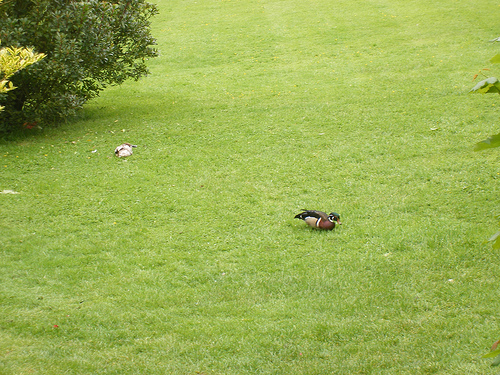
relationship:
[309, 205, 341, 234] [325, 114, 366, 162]
duck on grass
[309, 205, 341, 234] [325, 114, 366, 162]
duck in grass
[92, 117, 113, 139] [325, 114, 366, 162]
leaves in grass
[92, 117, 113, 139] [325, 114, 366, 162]
leaves on grass